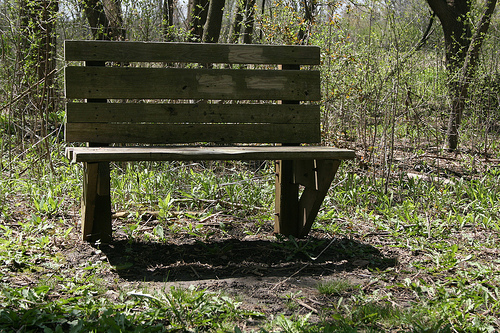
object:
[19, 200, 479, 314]
dirt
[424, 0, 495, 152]
trees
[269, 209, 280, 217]
bolts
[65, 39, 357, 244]
bench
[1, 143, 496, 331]
plants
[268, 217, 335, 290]
sticks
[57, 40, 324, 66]
planks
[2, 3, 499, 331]
photo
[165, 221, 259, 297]
patch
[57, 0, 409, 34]
sky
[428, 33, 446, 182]
plants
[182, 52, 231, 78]
gap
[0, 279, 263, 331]
grass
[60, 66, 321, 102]
wood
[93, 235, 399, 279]
shadow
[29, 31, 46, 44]
leaves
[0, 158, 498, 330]
ground